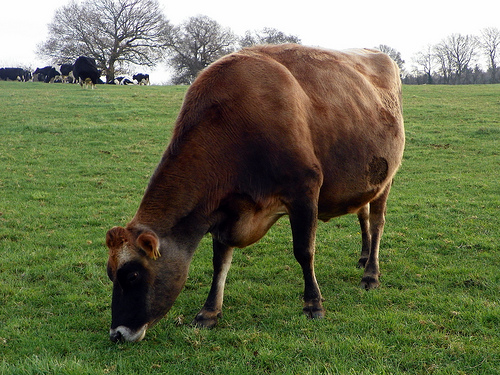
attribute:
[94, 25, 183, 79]
bare trees — grouped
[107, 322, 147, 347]
nose — white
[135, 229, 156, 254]
ear — brown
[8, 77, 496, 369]
grass — brown, green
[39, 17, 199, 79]
tree — bare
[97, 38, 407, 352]
cow — grazing, brown, black, enormous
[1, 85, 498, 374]
field — green, large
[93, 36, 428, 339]
cow — black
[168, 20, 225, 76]
tree — bare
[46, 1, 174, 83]
tree — bare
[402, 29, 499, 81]
tree — bare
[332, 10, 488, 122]
trees — bare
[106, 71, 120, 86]
trunk — brown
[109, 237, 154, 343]
face — multicolored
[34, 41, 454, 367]
cow — white, black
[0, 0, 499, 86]
sky — white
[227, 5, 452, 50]
sky — white, bright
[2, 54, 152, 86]
cow group — black and white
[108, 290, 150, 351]
cow snout — black, white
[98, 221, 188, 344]
face — white, brown, dark brown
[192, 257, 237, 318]
feet — white